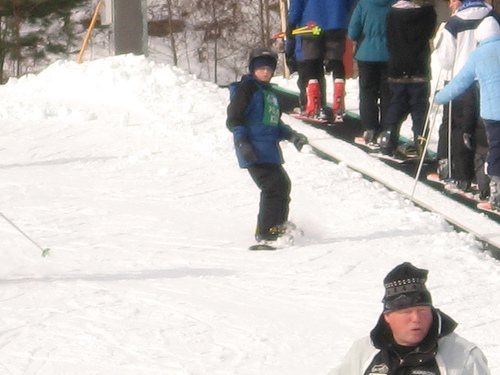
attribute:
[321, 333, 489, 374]
jacket — black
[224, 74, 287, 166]
jacket — teal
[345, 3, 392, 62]
jacket — blue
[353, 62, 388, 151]
pants — black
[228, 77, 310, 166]
jacket — blue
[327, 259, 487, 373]
man — white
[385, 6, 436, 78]
jacket — black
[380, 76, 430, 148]
pants — blue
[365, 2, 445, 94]
hoody — black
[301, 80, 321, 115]
boot — red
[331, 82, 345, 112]
boot — red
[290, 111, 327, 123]
ski — short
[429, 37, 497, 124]
jacket — pastel blue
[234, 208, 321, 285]
snowboards — row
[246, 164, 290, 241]
pants — warm, black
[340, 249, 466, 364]
man — grey, white, knitted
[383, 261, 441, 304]
hat — black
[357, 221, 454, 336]
hat — black, warm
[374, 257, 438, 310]
hat — black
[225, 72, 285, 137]
sleeves — black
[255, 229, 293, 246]
skate — white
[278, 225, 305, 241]
skate — white